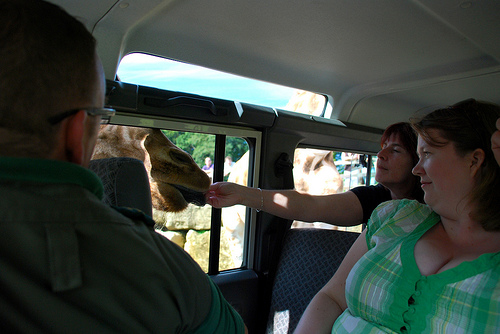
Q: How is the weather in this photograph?
A: It is cloudy.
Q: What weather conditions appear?
A: It is cloudy.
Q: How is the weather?
A: It is cloudy.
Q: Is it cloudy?
A: Yes, it is cloudy.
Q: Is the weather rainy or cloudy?
A: It is cloudy.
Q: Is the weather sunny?
A: No, it is cloudy.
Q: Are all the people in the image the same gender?
A: No, they are both male and female.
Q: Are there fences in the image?
A: No, there are no fences.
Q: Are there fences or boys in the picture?
A: No, there are no fences or boys.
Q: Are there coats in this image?
A: Yes, there is a coat.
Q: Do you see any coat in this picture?
A: Yes, there is a coat.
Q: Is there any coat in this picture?
A: Yes, there is a coat.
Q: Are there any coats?
A: Yes, there is a coat.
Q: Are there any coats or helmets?
A: Yes, there is a coat.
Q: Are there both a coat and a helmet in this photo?
A: No, there is a coat but no helmets.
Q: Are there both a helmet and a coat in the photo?
A: No, there is a coat but no helmets.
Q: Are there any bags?
A: No, there are no bags.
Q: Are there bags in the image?
A: No, there are no bags.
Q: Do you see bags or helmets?
A: No, there are no bags or helmets.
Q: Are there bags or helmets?
A: No, there are no bags or helmets.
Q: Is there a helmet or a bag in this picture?
A: No, there are no bags or helmets.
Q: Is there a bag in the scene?
A: No, there are no bags.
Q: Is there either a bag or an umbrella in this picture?
A: No, there are no bags or umbrellas.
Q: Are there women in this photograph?
A: Yes, there is a woman.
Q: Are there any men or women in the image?
A: Yes, there is a woman.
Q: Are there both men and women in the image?
A: Yes, there are both a woman and a man.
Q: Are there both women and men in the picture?
A: Yes, there are both a woman and a man.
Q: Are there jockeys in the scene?
A: No, there are no jockeys.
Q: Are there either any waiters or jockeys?
A: No, there are no jockeys or waiters.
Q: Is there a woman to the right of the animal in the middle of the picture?
A: Yes, there is a woman to the right of the animal.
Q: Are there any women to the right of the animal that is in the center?
A: Yes, there is a woman to the right of the animal.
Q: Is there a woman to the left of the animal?
A: No, the woman is to the right of the animal.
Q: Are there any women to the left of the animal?
A: No, the woman is to the right of the animal.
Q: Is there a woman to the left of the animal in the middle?
A: No, the woman is to the right of the animal.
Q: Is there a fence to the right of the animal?
A: No, there is a woman to the right of the animal.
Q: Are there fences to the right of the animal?
A: No, there is a woman to the right of the animal.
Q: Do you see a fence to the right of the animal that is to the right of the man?
A: No, there is a woman to the right of the animal.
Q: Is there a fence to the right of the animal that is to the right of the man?
A: No, there is a woman to the right of the animal.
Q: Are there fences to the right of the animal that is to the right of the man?
A: No, there is a woman to the right of the animal.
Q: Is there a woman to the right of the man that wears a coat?
A: Yes, there is a woman to the right of the man.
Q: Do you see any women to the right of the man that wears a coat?
A: Yes, there is a woman to the right of the man.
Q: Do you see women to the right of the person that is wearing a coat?
A: Yes, there is a woman to the right of the man.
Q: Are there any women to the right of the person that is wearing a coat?
A: Yes, there is a woman to the right of the man.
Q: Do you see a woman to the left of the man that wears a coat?
A: No, the woman is to the right of the man.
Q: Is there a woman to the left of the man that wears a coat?
A: No, the woman is to the right of the man.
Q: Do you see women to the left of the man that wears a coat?
A: No, the woman is to the right of the man.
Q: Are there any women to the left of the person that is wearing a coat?
A: No, the woman is to the right of the man.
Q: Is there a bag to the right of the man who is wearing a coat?
A: No, there is a woman to the right of the man.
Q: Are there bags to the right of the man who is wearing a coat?
A: No, there is a woman to the right of the man.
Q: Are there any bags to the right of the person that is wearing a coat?
A: No, there is a woman to the right of the man.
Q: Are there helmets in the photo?
A: No, there are no helmets.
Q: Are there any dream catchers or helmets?
A: No, there are no helmets or dream catchers.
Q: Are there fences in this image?
A: No, there are no fences.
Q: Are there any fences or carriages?
A: No, there are no fences or carriages.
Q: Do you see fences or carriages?
A: No, there are no fences or carriages.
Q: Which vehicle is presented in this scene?
A: The vehicle is a car.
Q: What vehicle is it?
A: The vehicle is a car.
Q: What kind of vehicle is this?
A: This is a car.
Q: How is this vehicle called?
A: This is a car.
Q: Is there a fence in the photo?
A: No, there are no fences.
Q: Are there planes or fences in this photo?
A: No, there are no fences or planes.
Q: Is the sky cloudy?
A: Yes, the sky is cloudy.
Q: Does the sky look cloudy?
A: Yes, the sky is cloudy.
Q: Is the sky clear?
A: No, the sky is cloudy.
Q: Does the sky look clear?
A: No, the sky is cloudy.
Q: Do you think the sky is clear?
A: No, the sky is cloudy.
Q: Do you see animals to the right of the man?
A: Yes, there is an animal to the right of the man.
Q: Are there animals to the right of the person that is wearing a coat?
A: Yes, there is an animal to the right of the man.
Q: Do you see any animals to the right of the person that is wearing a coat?
A: Yes, there is an animal to the right of the man.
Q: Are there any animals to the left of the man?
A: No, the animal is to the right of the man.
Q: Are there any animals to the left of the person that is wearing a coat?
A: No, the animal is to the right of the man.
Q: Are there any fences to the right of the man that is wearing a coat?
A: No, there is an animal to the right of the man.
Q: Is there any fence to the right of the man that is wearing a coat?
A: No, there is an animal to the right of the man.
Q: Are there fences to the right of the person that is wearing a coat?
A: No, there is an animal to the right of the man.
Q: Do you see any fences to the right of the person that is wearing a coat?
A: No, there is an animal to the right of the man.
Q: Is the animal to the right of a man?
A: Yes, the animal is to the right of a man.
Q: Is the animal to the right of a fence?
A: No, the animal is to the right of a man.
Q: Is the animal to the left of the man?
A: No, the animal is to the right of the man.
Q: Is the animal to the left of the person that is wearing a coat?
A: No, the animal is to the right of the man.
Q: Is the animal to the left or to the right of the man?
A: The animal is to the right of the man.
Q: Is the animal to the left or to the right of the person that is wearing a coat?
A: The animal is to the right of the man.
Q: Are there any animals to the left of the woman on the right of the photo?
A: Yes, there is an animal to the left of the woman.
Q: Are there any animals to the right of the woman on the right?
A: No, the animal is to the left of the woman.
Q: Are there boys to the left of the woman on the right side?
A: No, there is an animal to the left of the woman.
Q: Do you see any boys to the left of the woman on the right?
A: No, there is an animal to the left of the woman.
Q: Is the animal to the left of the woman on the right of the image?
A: Yes, the animal is to the left of the woman.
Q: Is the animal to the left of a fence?
A: No, the animal is to the left of the woman.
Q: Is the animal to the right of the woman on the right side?
A: No, the animal is to the left of the woman.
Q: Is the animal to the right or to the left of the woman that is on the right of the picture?
A: The animal is to the left of the woman.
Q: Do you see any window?
A: Yes, there is a window.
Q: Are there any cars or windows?
A: Yes, there is a window.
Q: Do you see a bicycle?
A: No, there are no bicycles.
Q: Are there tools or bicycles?
A: No, there are no bicycles or tools.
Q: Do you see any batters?
A: No, there are no batters.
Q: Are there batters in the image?
A: No, there are no batters.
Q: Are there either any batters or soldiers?
A: No, there are no batters or soldiers.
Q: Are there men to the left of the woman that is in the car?
A: Yes, there is a man to the left of the woman.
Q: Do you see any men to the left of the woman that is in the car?
A: Yes, there is a man to the left of the woman.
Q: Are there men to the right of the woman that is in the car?
A: No, the man is to the left of the woman.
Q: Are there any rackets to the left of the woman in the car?
A: No, there is a man to the left of the woman.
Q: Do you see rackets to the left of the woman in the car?
A: No, there is a man to the left of the woman.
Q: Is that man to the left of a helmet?
A: No, the man is to the left of a woman.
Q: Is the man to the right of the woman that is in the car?
A: No, the man is to the left of the woman.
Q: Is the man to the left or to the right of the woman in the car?
A: The man is to the left of the woman.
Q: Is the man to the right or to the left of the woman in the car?
A: The man is to the left of the woman.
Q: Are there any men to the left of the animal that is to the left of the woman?
A: Yes, there is a man to the left of the animal.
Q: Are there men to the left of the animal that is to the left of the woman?
A: Yes, there is a man to the left of the animal.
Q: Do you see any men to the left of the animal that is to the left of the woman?
A: Yes, there is a man to the left of the animal.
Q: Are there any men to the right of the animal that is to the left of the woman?
A: No, the man is to the left of the animal.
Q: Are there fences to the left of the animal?
A: No, there is a man to the left of the animal.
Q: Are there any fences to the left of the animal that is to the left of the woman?
A: No, there is a man to the left of the animal.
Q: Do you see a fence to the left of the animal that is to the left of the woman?
A: No, there is a man to the left of the animal.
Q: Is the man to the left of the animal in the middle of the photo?
A: Yes, the man is to the left of the animal.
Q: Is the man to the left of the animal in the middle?
A: Yes, the man is to the left of the animal.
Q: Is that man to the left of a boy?
A: No, the man is to the left of the animal.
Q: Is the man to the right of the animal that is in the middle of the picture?
A: No, the man is to the left of the animal.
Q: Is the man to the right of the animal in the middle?
A: No, the man is to the left of the animal.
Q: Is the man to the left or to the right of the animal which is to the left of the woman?
A: The man is to the left of the animal.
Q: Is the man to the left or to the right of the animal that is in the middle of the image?
A: The man is to the left of the animal.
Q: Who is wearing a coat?
A: The man is wearing a coat.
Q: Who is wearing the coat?
A: The man is wearing a coat.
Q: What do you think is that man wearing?
A: The man is wearing a coat.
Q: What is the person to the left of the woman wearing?
A: The man is wearing a coat.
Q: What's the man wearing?
A: The man is wearing a coat.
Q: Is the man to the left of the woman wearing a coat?
A: Yes, the man is wearing a coat.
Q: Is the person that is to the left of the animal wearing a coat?
A: Yes, the man is wearing a coat.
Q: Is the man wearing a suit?
A: No, the man is wearing a coat.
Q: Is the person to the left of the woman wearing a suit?
A: No, the man is wearing a coat.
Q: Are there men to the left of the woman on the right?
A: Yes, there is a man to the left of the woman.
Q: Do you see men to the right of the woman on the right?
A: No, the man is to the left of the woman.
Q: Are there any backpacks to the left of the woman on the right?
A: No, there is a man to the left of the woman.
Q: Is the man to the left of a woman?
A: Yes, the man is to the left of a woman.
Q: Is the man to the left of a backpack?
A: No, the man is to the left of a woman.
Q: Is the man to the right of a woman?
A: No, the man is to the left of a woman.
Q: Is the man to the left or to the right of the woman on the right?
A: The man is to the left of the woman.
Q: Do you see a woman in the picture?
A: Yes, there is a woman.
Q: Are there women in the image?
A: Yes, there is a woman.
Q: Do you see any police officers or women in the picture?
A: Yes, there is a woman.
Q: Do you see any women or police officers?
A: Yes, there is a woman.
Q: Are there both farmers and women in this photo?
A: No, there is a woman but no farmers.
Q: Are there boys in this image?
A: No, there are no boys.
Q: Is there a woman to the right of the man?
A: Yes, there is a woman to the right of the man.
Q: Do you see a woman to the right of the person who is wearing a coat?
A: Yes, there is a woman to the right of the man.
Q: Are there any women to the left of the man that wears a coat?
A: No, the woman is to the right of the man.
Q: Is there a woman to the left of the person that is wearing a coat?
A: No, the woman is to the right of the man.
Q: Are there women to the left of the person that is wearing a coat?
A: No, the woman is to the right of the man.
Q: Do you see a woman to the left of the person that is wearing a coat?
A: No, the woman is to the right of the man.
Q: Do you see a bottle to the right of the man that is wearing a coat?
A: No, there is a woman to the right of the man.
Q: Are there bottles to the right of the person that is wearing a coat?
A: No, there is a woman to the right of the man.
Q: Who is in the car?
A: The woman is in the car.